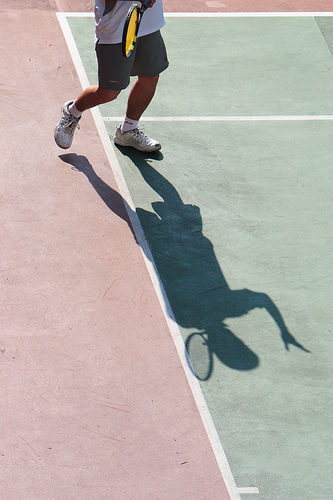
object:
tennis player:
[52, 0, 169, 155]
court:
[0, 1, 331, 499]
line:
[54, 11, 239, 499]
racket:
[121, 1, 153, 61]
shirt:
[93, 0, 164, 47]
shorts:
[95, 27, 170, 91]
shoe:
[113, 122, 162, 155]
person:
[52, 1, 169, 153]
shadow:
[57, 152, 311, 383]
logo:
[108, 76, 121, 82]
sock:
[119, 114, 138, 130]